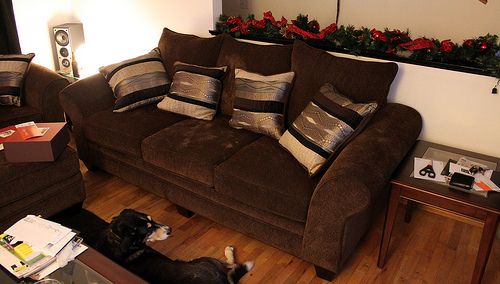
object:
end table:
[374, 139, 500, 284]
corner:
[211, 0, 274, 19]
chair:
[1, 50, 89, 230]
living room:
[0, 0, 500, 284]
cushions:
[212, 135, 321, 223]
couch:
[55, 25, 425, 282]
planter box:
[210, 4, 500, 77]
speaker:
[46, 13, 86, 79]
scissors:
[419, 159, 437, 178]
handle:
[427, 167, 436, 178]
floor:
[72, 154, 500, 284]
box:
[0, 121, 71, 164]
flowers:
[229, 27, 239, 33]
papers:
[414, 157, 448, 183]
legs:
[374, 184, 401, 269]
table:
[0, 216, 164, 284]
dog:
[90, 206, 258, 283]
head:
[106, 207, 172, 245]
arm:
[303, 102, 425, 217]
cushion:
[277, 81, 381, 179]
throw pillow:
[0, 47, 37, 109]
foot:
[224, 246, 234, 256]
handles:
[418, 166, 429, 176]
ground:
[56, 141, 500, 283]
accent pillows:
[95, 50, 171, 113]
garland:
[288, 23, 338, 40]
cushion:
[228, 64, 294, 140]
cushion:
[155, 60, 231, 122]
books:
[0, 214, 73, 265]